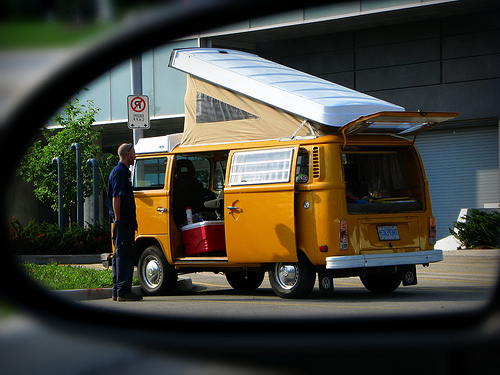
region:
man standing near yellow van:
[106, 143, 146, 301]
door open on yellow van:
[168, 147, 230, 262]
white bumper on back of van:
[324, 246, 445, 273]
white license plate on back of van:
[376, 220, 401, 242]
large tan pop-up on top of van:
[178, 73, 320, 145]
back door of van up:
[337, 107, 456, 142]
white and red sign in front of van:
[126, 91, 153, 130]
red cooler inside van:
[182, 216, 224, 258]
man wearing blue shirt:
[108, 161, 136, 223]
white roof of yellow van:
[168, 44, 410, 131]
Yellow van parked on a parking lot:
[100, 96, 465, 313]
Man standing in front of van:
[100, 137, 148, 307]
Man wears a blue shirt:
[97, 129, 156, 310]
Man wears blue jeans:
[100, 137, 150, 312]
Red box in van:
[176, 214, 229, 257]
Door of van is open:
[221, 150, 305, 270]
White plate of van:
[370, 219, 407, 244]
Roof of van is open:
[169, 37, 394, 122]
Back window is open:
[336, 105, 461, 145]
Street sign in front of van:
[119, 89, 153, 134]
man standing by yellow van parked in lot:
[72, 15, 442, 323]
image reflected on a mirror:
[12, 35, 483, 351]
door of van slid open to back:
[135, 146, 336, 281]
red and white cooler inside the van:
[170, 190, 230, 270]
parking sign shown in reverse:
[105, 80, 160, 131]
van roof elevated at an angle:
[175, 41, 410, 141]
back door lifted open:
[325, 100, 465, 245]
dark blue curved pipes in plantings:
[35, 136, 106, 246]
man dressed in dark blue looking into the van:
[96, 125, 146, 305]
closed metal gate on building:
[370, 107, 492, 262]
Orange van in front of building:
[107, 124, 448, 302]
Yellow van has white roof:
[140, 44, 404, 149]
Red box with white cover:
[174, 211, 225, 258]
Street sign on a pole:
[125, 91, 156, 133]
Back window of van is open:
[337, 108, 449, 216]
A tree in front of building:
[25, 92, 103, 237]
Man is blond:
[94, 133, 153, 308]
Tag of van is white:
[371, 220, 402, 244]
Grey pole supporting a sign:
[125, 48, 150, 150]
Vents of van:
[310, 140, 321, 190]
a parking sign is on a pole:
[125, 95, 150, 132]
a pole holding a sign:
[123, 56, 148, 266]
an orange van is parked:
[110, 130, 435, 301]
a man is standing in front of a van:
[110, 140, 141, 300]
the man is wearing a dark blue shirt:
[106, 164, 136, 217]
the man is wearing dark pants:
[113, 216, 133, 292]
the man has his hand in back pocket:
[110, 205, 127, 229]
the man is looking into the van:
[109, 141, 141, 303]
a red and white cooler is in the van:
[178, 221, 225, 256]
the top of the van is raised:
[165, 41, 409, 143]